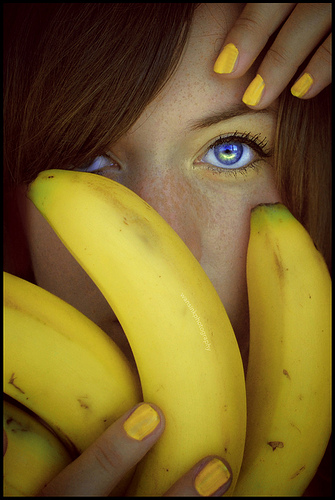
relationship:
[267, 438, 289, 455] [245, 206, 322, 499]
spot on banana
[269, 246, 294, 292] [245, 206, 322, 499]
line on banana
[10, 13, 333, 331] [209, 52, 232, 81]
girl has fingernail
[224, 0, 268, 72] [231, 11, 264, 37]
finger with groves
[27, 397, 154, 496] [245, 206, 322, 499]
finger on banana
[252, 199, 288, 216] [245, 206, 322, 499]
tip of banana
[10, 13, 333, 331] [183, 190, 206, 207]
girl has freckle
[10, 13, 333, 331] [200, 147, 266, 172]
girl has eye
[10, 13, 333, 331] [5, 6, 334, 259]
girl has hair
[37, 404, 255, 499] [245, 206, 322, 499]
hand holding banana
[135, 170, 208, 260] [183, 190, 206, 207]
nose has freckle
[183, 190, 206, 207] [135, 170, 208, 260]
freckle on nose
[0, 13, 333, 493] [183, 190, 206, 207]
girl with freckle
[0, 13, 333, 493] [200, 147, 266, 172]
girl has eye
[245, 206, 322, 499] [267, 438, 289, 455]
banana has spot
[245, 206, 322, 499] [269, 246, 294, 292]
banana has line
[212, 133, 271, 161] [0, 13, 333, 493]
eyelash of girl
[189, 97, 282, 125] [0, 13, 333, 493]
eyebrow of girl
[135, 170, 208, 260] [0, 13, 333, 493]
nose of girl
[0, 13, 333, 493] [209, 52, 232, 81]
girl has fingernail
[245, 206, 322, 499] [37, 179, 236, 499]
banana together with banana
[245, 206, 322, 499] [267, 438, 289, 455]
banana with spot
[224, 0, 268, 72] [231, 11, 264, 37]
finger has groves